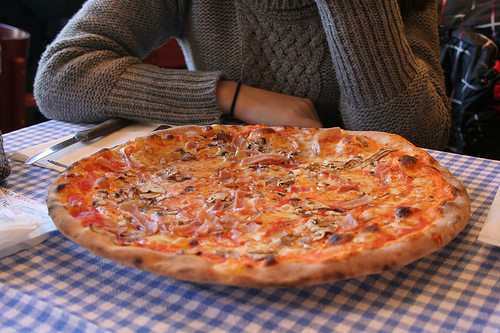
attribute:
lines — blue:
[29, 272, 132, 316]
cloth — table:
[14, 121, 492, 331]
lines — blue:
[63, 270, 168, 330]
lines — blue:
[183, 296, 364, 330]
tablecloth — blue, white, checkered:
[13, 121, 498, 331]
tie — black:
[221, 78, 245, 120]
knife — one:
[3, 104, 133, 169]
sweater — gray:
[27, 4, 426, 134]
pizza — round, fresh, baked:
[40, 121, 466, 281]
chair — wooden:
[2, 10, 35, 130]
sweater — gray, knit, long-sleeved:
[28, 6, 450, 128]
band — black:
[224, 74, 247, 114]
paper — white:
[13, 122, 156, 167]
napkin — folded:
[472, 173, 499, 243]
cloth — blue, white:
[19, 271, 159, 327]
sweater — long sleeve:
[21, 0, 461, 147]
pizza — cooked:
[41, 111, 479, 292]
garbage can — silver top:
[2, 14, 36, 123]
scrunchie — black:
[224, 76, 245, 116]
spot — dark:
[392, 198, 419, 219]